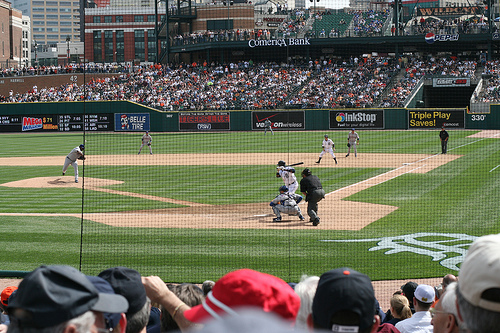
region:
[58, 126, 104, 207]
pitcher is throwing the baseball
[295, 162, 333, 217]
umpire is behind the catcher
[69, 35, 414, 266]
net behind the baseball umpire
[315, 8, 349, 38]
stadium seats are green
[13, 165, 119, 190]
pitching mound on the field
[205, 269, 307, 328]
hat is red with two white stripes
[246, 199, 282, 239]
home plate is on the ground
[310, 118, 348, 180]
baseball player ready to run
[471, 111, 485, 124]
330 written on the wall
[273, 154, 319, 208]
batter waiting for the pitch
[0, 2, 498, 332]
a baseball game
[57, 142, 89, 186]
a pitcher throwing a ball from the pitcher's mound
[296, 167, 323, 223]
the home plate umpire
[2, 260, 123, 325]
a man's baseball cap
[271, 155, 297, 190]
the player at bat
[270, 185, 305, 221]
the catcher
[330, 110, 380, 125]
an Ink Stop advertisement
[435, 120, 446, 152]
the first base umpire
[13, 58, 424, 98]
fans in the stands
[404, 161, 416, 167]
first base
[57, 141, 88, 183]
baseball player is pitching a ball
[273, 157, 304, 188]
baseball player getting ready to swing the bat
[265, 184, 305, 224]
the umpire is crouching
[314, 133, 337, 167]
baseball player getting ready to run to the next base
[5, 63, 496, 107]
the stadium is full of fans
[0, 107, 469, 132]
advertisements on the wall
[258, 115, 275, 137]
baseball player in the outfield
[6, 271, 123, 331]
man wearing a black hat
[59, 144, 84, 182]
baseball player has grey uniform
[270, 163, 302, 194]
baseball player has white uniform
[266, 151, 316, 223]
batter swinging the bat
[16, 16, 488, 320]
they are plaing a professional baseball game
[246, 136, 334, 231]
the opponent is trying to hit the ball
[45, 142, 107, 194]
the pitcher is throwing the ball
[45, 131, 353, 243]
the pitcher and catcher are talking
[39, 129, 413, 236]
each team wants to win the game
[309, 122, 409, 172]
the first base man is paying attention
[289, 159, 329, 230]
the ump is watching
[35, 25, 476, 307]
the game is going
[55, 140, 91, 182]
The pitcher is throwing the ball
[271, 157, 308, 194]
Batter is holding the bat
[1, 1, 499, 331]
The photo was taken at a baseball stadium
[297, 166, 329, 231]
The umpire stands behind the catcher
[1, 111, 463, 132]
The back wall is lined with advertisements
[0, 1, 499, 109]
The far side of the stadium is filled with fans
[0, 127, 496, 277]
The grass is well manicured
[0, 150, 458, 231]
The dirt is light brown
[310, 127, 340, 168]
The player is leading off first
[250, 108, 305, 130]
Verizon Wireless advertises on the wall